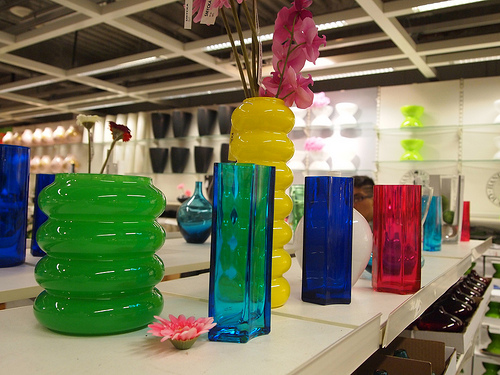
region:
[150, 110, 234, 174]
Black vases on wall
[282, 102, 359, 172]
White vases on wall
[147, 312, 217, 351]
Pink decorative flower on shelf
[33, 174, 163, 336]
Light green rippled vase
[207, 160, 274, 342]
Tall blue glass vase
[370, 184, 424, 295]
Tall pink glass vase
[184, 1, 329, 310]
Yellow rippled vase with pink flowers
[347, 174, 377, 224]
Person standing behind shelves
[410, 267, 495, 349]
Row of dark vases on shelf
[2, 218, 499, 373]
White shelves underneath vases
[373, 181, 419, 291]
a long narrow dark pink translucent glass vase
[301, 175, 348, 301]
long narrow royal blue glass vase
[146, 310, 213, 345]
the top of a pink flower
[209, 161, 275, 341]
long narrow medium blue glass vase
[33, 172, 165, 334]
a frosted green glass vase with a stacked appearance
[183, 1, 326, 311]
pink flowers emerging from a yellow glass vase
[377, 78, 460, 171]
lime green vases on shelves in background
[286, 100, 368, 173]
white vases on shelves in background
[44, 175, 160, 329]
this is a vase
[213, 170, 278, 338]
this is a vase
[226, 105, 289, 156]
this is a vase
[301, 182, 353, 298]
this is a vase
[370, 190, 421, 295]
this is a vase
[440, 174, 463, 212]
this is a vase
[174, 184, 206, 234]
this is a vase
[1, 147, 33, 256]
this is a vase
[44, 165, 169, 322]
this is a vase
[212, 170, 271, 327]
this is a vase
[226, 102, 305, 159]
this is a vase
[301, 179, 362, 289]
this is a vase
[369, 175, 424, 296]
this is a vase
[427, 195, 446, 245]
this is a vase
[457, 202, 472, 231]
this is a vase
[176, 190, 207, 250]
this is a vase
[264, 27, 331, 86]
this is a flower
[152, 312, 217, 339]
the flowers are pink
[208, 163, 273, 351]
the vase is blue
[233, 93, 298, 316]
the vase is yellow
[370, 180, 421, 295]
the vase is red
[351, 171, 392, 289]
the man has glasse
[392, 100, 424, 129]
the object is green in color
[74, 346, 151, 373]
the surface is white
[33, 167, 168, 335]
green vase on a counter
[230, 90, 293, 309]
tall yellow vase on a counter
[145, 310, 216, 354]
plastic flower on a counter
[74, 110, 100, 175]
white flower in a green vase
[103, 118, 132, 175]
red flower in a green vase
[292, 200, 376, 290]
white vase on the counter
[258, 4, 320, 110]
pink flower in a yellow vase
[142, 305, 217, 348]
Small pink flower on a shelf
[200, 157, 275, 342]
Clear blue vase next to a yellow vase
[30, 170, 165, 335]
Green vase next to a blue clear vase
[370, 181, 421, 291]
Red vase next to a white vase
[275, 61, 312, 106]
Pink flower next to a yellow vase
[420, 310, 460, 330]
Small light bulb in a drawer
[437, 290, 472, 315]
Small light bulb in a drawer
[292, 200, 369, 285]
White vase next to a red vase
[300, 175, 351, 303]
Blue vase next to a yellow vase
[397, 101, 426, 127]
Green stool sitting on a shelf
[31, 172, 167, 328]
colorful glass vase on the white table